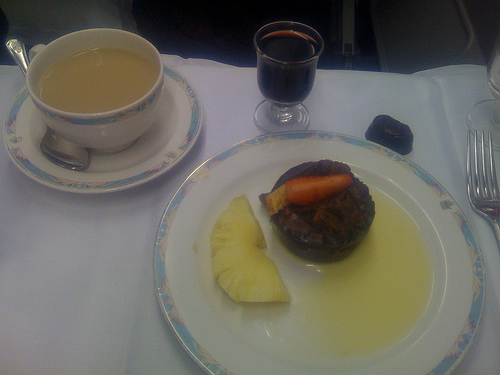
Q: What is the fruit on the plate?
A: Pineapple.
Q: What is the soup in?
A: A bowl.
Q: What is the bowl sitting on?
A: A saucer.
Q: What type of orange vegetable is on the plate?
A: A carrot.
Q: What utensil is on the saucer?
A: A spoon.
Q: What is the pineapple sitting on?
A: A plate.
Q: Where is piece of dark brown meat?
A: On plate.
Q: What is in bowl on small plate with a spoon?
A: Bowl of soup.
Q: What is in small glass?
A: Wine.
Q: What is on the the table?
A: White dinner table cloth.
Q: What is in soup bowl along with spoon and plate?
A: Soup.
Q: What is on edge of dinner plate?
A: Design.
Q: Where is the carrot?
A: On the meat.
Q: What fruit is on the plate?
A: Pineapple.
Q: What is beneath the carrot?
A: Meat.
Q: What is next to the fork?
A: The plate.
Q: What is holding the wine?
A: The glass.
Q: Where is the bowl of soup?
A: On the left.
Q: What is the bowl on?
A: A white saucer.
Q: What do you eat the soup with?
A: The spoon.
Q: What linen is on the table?
A: Tablecloth.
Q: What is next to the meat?
A: A pineapple.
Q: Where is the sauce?
A: Under the meat.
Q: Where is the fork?
A: To the right of the plate.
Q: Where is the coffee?
A: In the coffee cup.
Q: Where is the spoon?
A: Next to the cup.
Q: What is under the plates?
A: White tablecloth.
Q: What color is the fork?
A: Silver.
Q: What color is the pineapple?
A: Yellow.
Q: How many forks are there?
A: One.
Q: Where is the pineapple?
A: On the plate.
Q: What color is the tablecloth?
A: White.